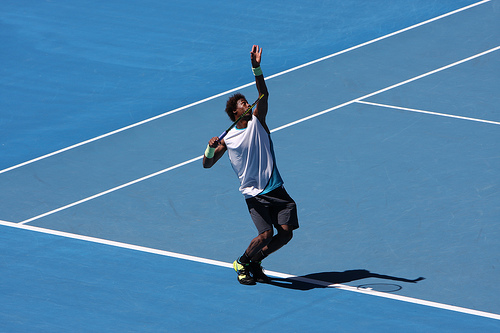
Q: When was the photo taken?
A: Daytime.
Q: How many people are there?
A: One.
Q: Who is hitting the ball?
A: Tennis player.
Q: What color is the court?
A: Blue.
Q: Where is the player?
A: On the court.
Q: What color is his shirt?
A: White.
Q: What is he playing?
A: Tennis.